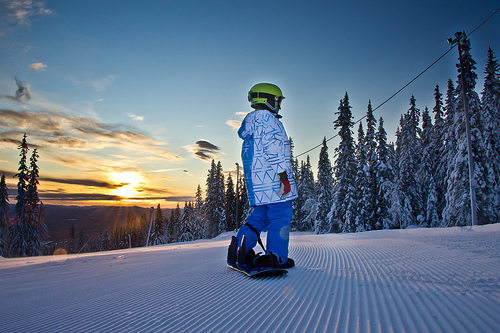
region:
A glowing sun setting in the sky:
[101, 161, 148, 205]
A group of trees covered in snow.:
[293, 34, 498, 236]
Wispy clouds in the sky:
[1, 75, 180, 160]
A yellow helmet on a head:
[246, 83, 286, 109]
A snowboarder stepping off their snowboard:
[226, 82, 298, 276]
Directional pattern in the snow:
[12, 225, 494, 330]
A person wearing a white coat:
[238, 110, 300, 205]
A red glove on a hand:
[279, 170, 291, 195]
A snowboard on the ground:
[221, 232, 287, 277]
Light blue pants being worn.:
[233, 200, 293, 265]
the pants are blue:
[238, 203, 295, 243]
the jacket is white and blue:
[231, 117, 300, 204]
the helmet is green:
[248, 82, 288, 110]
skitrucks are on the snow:
[317, 257, 382, 329]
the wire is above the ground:
[350, 61, 432, 109]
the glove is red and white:
[274, 179, 298, 206]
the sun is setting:
[85, 173, 151, 205]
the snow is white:
[368, 240, 445, 331]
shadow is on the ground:
[306, 262, 375, 318]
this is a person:
[201, 60, 330, 316]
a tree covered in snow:
[412, 30, 489, 249]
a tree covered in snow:
[481, 42, 498, 224]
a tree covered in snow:
[439, 56, 466, 232]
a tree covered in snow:
[381, 88, 443, 238]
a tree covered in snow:
[352, 88, 372, 242]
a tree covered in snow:
[304, 128, 329, 221]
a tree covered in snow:
[326, 85, 374, 224]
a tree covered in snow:
[304, 125, 339, 235]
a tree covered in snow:
[197, 159, 249, 259]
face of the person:
[241, 74, 294, 113]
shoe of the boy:
[229, 230, 299, 281]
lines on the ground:
[320, 265, 361, 325]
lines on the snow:
[315, 260, 361, 320]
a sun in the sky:
[67, 153, 196, 233]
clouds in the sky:
[24, 160, 105, 190]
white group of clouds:
[6, 93, 116, 146]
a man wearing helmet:
[230, 62, 304, 106]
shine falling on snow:
[121, 220, 215, 252]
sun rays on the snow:
[59, 225, 196, 266]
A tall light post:
[444, 28, 479, 228]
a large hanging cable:
[293, 4, 495, 160]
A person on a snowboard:
[223, 79, 298, 269]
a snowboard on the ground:
[223, 235, 288, 280]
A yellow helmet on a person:
[245, 80, 286, 110]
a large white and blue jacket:
[236, 107, 302, 207]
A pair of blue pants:
[235, 200, 293, 261]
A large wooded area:
[0, 29, 498, 256]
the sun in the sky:
[109, 173, 142, 200]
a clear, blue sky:
[1, 1, 498, 207]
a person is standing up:
[234, 77, 300, 273]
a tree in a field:
[444, 38, 494, 226]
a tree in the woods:
[396, 95, 436, 214]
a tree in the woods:
[350, 154, 380, 233]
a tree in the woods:
[328, 94, 365, 239]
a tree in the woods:
[307, 135, 338, 231]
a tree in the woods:
[473, 47, 498, 140]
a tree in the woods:
[206, 160, 227, 233]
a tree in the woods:
[188, 181, 207, 243]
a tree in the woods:
[12, 131, 46, 259]